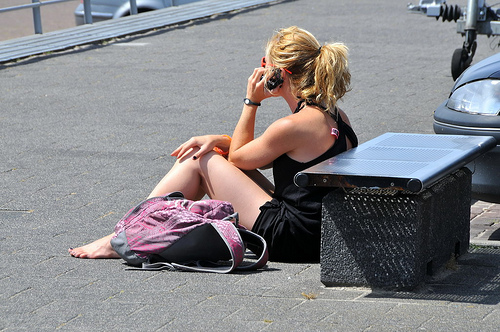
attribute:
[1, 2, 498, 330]
walkway — part , tile 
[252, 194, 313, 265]
shorts —  woman's black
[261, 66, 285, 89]
cell phone — cell  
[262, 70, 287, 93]
cell phone — cell  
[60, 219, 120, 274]
foot — woman's , bare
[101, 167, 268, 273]
backpack — black, pink 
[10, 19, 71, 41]
bench — concrete 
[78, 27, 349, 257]
woman — blonde 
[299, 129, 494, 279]
bench — against 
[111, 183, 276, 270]
backpack —  gray, pink 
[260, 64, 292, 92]
phone — black 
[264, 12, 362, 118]
hair — woman's blonde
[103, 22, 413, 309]
woman — blonde 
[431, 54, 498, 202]
car — blue , black 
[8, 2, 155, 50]
guard rail — gray metal guard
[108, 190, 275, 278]
backpack — purple 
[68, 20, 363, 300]
woman — behind 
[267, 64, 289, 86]
ear — woman's 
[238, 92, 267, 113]
wristwatch — woman's black 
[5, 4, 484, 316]
ground — concrete 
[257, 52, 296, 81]
sunglasses — orange 